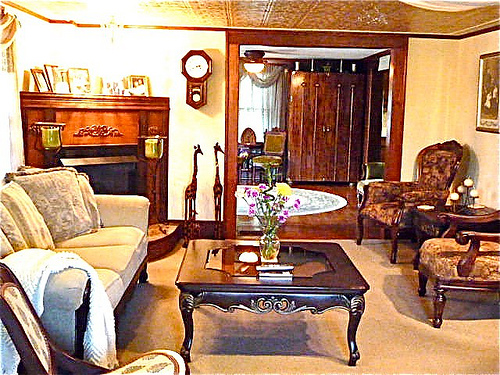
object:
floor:
[41, 230, 496, 372]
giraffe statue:
[213, 142, 226, 225]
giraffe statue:
[184, 144, 203, 228]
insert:
[204, 246, 333, 277]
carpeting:
[114, 238, 498, 373]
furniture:
[0, 263, 188, 375]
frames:
[30, 68, 51, 92]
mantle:
[19, 90, 168, 225]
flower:
[276, 183, 293, 197]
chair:
[247, 127, 288, 187]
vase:
[258, 224, 280, 259]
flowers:
[294, 203, 299, 210]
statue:
[213, 142, 226, 235]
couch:
[0, 166, 151, 361]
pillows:
[14, 170, 93, 243]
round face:
[185, 55, 209, 79]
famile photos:
[128, 74, 150, 95]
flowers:
[252, 191, 258, 197]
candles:
[449, 179, 479, 214]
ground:
[114, 186, 500, 375]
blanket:
[0, 248, 119, 375]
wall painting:
[476, 55, 499, 130]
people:
[483, 78, 498, 109]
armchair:
[416, 210, 499, 328]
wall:
[404, 33, 499, 208]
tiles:
[243, 7, 405, 34]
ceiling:
[9, 2, 499, 52]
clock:
[181, 50, 213, 109]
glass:
[205, 245, 333, 277]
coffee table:
[174, 238, 369, 366]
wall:
[2, 3, 227, 238]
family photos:
[67, 68, 92, 95]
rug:
[236, 184, 348, 218]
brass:
[228, 51, 366, 111]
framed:
[391, 146, 464, 263]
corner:
[372, 114, 451, 243]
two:
[354, 140, 500, 328]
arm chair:
[356, 140, 468, 264]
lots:
[31, 64, 154, 102]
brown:
[362, 181, 398, 198]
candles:
[238, 251, 258, 264]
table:
[410, 204, 500, 271]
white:
[73, 264, 115, 364]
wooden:
[181, 50, 213, 110]